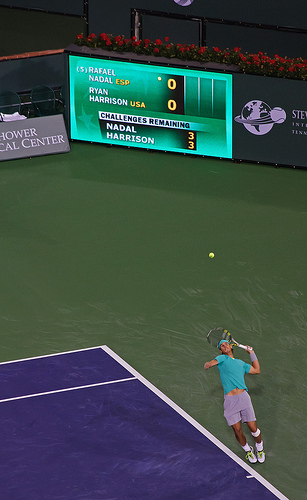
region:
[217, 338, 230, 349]
The man is wearing a blue headband.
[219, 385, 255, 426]
The man is wearing grey shorts.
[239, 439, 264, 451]
The man is wearing white socks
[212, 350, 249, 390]
The man is wearing a blue t-shirt.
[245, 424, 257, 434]
The man is wearing a white leg wrap.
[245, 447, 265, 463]
The man is wearing white shoes.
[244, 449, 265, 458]
The man's shoes have yellow laces.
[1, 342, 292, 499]
The tennis court is blue.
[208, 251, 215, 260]
The tennis ball is yellow.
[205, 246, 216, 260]
The tennis ball is above the man's head.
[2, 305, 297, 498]
it is tennis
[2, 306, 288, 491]
it is a tennis court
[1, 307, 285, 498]
the player is holding a racket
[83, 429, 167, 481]
the court is blue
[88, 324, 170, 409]
the court lines are white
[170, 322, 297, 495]
the player is a man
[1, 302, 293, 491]
it is a daytime scene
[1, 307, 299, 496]
it is an outdoor scene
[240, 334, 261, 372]
the player has a band on his hand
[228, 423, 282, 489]
the player is wearing sneakers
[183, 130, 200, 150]
yellow numbers on board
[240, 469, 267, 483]
small white line on court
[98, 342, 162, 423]
solid white edge on court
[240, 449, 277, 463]
yellow laces on sneakers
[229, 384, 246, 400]
man's belly button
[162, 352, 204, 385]
green exterior asphalt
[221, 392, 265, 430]
man's gray tennis shorts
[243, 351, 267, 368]
purple wristband on man's hand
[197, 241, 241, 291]
yellow tennis ball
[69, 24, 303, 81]
A row of red flowers.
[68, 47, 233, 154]
A digital scoreboard.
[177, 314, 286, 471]
A man playing tennis.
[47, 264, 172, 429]
The tennis court.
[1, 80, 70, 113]
Chairs.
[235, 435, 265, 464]
The man is wearing white socks.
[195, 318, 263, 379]
The man has a tennis racket in his left hand.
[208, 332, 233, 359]
The man is wearing is a headband.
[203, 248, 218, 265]
Tennis ball.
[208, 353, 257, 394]
The man's shirt is teal.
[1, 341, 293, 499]
tennis court is blue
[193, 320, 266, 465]
tennis player swinging racket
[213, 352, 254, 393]
tennis player wearing blue shirt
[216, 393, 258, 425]
tennis player wearing grey shorts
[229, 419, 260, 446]
tennis player has very tan legs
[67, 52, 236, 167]
green scoreboard on wall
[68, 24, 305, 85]
red flowers on wall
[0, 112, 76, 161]
grey sign in background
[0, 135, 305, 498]
green tennis court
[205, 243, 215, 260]
tennis ball in mid-air